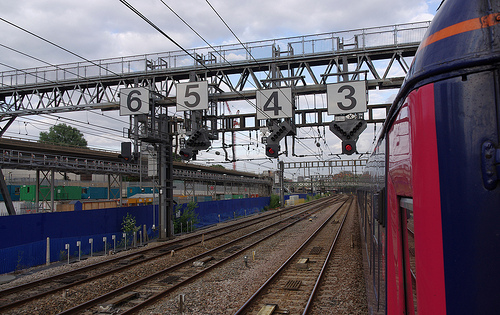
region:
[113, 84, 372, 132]
numbers sitting above the tracks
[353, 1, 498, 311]
the blue and red train sitting on the track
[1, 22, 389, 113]
the metal poles above the tracks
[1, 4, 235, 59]
the power lines above the tracks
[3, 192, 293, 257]
the fence next to the tracks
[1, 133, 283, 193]
a bridge next to the tracks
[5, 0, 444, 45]
the cloudy sky above everything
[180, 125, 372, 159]
the red lights above the tracks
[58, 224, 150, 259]
tiny poles next to the tracks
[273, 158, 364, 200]
more metal poles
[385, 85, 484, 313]
this is a train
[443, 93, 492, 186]
the train is blue in color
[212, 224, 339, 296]
these are the rails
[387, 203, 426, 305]
the window is closed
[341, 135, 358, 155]
the light is on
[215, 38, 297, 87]
this is a bridge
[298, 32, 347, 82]
the bridge is metallic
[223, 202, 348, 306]
the rails are empty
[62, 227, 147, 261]
the poles are short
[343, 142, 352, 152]
the light is red in color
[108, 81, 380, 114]
train track numbers six to three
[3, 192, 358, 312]
multiple empty train tracks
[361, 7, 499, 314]
a purple, orange, and magenta train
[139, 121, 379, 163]
a bunch of train signal lights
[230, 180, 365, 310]
empty track number four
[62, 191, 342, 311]
empty track number five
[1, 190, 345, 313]
empty track number six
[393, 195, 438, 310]
window on the train on track three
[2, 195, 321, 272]
a blue divider between the tracks and the street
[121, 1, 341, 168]
multiple wires that the trains run on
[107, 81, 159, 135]
the number six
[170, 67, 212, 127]
the number five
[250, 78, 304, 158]
the number four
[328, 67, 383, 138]
the number three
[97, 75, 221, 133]
the number sixty five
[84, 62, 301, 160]
the number six fifty four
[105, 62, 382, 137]
the number six thousand five hundred and forty three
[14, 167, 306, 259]
a long blue wall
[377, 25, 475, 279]
a black and red train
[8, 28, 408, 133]
a suspension bridge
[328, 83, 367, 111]
black and white sign reading 3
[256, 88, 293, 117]
black and white sign reading 4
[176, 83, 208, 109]
black and white sign reading 5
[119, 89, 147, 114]
black and white sign reading 6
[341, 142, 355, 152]
red signal light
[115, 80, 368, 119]
black and white signs with a number on each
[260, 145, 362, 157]
two red signal lights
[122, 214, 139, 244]
green plants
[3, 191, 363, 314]
empty railroad tracks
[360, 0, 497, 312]
dark pink and royal blue train